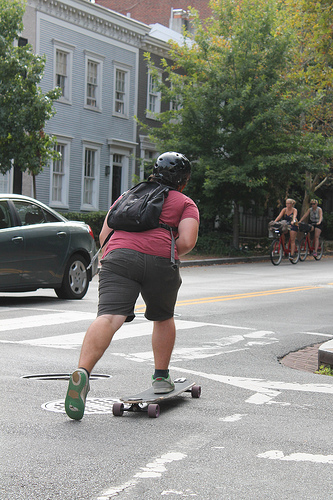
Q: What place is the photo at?
A: It is at the street.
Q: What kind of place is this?
A: It is a street.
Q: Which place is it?
A: It is a street.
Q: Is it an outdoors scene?
A: Yes, it is outdoors.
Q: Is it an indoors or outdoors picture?
A: It is outdoors.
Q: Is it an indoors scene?
A: No, it is outdoors.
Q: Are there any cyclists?
A: Yes, there is a cyclist.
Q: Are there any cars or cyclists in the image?
A: Yes, there is a cyclist.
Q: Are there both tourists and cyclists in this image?
A: No, there is a cyclist but no tourists.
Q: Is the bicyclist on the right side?
A: Yes, the bicyclist is on the right of the image.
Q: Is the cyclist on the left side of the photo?
A: No, the cyclist is on the right of the image.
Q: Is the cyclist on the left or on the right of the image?
A: The cyclist is on the right of the image.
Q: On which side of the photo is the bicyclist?
A: The bicyclist is on the right of the image.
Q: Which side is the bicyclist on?
A: The bicyclist is on the right of the image.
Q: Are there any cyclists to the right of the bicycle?
A: Yes, there is a cyclist to the right of the bicycle.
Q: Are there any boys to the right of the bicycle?
A: No, there is a cyclist to the right of the bicycle.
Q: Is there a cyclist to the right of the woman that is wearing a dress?
A: Yes, there is a cyclist to the right of the woman.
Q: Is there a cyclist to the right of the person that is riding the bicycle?
A: Yes, there is a cyclist to the right of the woman.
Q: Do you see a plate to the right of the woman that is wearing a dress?
A: No, there is a cyclist to the right of the woman.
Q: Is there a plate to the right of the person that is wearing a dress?
A: No, there is a cyclist to the right of the woman.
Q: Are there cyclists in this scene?
A: Yes, there is a cyclist.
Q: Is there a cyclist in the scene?
A: Yes, there is a cyclist.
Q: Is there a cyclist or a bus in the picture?
A: Yes, there is a cyclist.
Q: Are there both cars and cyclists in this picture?
A: Yes, there are both a cyclist and a car.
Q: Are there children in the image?
A: No, there are no children.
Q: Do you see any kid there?
A: No, there are no children.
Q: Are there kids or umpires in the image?
A: No, there are no kids or umpires.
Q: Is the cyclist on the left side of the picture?
A: No, the cyclist is on the right of the image.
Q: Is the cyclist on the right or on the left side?
A: The cyclist is on the right of the image.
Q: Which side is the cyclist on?
A: The cyclist is on the right of the image.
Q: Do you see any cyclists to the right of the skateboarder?
A: Yes, there is a cyclist to the right of the skateboarder.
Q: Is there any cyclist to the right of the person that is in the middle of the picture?
A: Yes, there is a cyclist to the right of the skateboarder.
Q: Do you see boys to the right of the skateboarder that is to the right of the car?
A: No, there is a cyclist to the right of the skateboarder.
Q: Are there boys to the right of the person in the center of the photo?
A: No, there is a cyclist to the right of the skateboarder.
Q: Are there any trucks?
A: No, there are no trucks.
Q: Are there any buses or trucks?
A: No, there are no trucks or buses.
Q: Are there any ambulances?
A: No, there are no ambulances.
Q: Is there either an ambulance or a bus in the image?
A: No, there are no ambulances or buses.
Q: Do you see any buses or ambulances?
A: No, there are no ambulances or buses.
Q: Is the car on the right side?
A: No, the car is on the left of the image.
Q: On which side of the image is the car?
A: The car is on the left of the image.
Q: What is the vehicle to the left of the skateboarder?
A: The vehicle is a car.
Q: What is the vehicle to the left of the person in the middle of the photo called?
A: The vehicle is a car.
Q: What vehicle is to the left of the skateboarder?
A: The vehicle is a car.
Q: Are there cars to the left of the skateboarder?
A: Yes, there is a car to the left of the skateboarder.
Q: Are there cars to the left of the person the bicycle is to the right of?
A: Yes, there is a car to the left of the skateboarder.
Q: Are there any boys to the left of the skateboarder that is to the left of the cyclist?
A: No, there is a car to the left of the skateboarder.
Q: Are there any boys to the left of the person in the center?
A: No, there is a car to the left of the skateboarder.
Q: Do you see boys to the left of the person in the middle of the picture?
A: No, there is a car to the left of the skateboarder.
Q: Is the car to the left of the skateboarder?
A: Yes, the car is to the left of the skateboarder.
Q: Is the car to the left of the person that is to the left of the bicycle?
A: Yes, the car is to the left of the skateboarder.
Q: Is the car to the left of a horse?
A: No, the car is to the left of the skateboarder.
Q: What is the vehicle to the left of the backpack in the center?
A: The vehicle is a car.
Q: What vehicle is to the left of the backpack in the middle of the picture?
A: The vehicle is a car.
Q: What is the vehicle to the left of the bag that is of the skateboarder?
A: The vehicle is a car.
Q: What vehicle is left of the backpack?
A: The vehicle is a car.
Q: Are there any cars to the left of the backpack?
A: Yes, there is a car to the left of the backpack.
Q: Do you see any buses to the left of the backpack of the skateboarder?
A: No, there is a car to the left of the backpack.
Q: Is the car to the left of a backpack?
A: Yes, the car is to the left of a backpack.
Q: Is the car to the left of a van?
A: No, the car is to the left of a backpack.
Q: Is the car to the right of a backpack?
A: No, the car is to the left of a backpack.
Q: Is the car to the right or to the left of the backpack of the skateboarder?
A: The car is to the left of the backpack.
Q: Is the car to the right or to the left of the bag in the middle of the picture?
A: The car is to the left of the backpack.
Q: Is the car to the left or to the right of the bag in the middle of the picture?
A: The car is to the left of the backpack.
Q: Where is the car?
A: The car is in the street.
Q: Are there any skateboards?
A: Yes, there is a skateboard.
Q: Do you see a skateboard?
A: Yes, there is a skateboard.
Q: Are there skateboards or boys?
A: Yes, there is a skateboard.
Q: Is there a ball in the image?
A: No, there are no balls.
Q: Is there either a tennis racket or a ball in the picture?
A: No, there are no balls or rackets.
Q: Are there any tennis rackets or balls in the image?
A: No, there are no balls or tennis rackets.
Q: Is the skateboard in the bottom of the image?
A: Yes, the skateboard is in the bottom of the image.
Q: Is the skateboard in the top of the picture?
A: No, the skateboard is in the bottom of the image.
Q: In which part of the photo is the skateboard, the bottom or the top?
A: The skateboard is in the bottom of the image.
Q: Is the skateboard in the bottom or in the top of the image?
A: The skateboard is in the bottom of the image.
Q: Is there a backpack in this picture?
A: Yes, there is a backpack.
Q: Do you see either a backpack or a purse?
A: Yes, there is a backpack.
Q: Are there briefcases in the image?
A: No, there are no briefcases.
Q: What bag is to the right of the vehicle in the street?
A: The bag is a backpack.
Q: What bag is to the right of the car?
A: The bag is a backpack.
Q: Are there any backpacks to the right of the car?
A: Yes, there is a backpack to the right of the car.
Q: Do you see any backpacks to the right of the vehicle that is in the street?
A: Yes, there is a backpack to the right of the car.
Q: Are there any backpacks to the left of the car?
A: No, the backpack is to the right of the car.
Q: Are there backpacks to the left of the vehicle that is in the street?
A: No, the backpack is to the right of the car.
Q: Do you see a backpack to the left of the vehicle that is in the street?
A: No, the backpack is to the right of the car.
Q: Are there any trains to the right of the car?
A: No, there is a backpack to the right of the car.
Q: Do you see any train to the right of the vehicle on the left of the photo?
A: No, there is a backpack to the right of the car.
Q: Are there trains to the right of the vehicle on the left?
A: No, there is a backpack to the right of the car.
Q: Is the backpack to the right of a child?
A: No, the backpack is to the right of the car.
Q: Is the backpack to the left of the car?
A: No, the backpack is to the right of the car.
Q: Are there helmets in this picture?
A: Yes, there is a helmet.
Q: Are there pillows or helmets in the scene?
A: Yes, there is a helmet.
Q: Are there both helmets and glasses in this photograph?
A: No, there is a helmet but no glasses.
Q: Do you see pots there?
A: No, there are no pots.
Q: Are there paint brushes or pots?
A: No, there are no pots or paint brushes.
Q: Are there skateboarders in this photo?
A: Yes, there is a skateboarder.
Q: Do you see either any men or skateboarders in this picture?
A: Yes, there is a skateboarder.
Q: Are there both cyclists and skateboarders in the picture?
A: Yes, there are both a skateboarder and a cyclist.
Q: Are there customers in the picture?
A: No, there are no customers.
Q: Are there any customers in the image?
A: No, there are no customers.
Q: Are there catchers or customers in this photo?
A: No, there are no customers or catchers.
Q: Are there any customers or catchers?
A: No, there are no customers or catchers.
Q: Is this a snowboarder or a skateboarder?
A: This is a skateboarder.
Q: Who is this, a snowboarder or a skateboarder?
A: This is a skateboarder.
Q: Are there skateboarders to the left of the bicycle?
A: Yes, there is a skateboarder to the left of the bicycle.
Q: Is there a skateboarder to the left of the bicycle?
A: Yes, there is a skateboarder to the left of the bicycle.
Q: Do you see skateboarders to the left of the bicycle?
A: Yes, there is a skateboarder to the left of the bicycle.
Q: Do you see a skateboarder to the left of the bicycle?
A: Yes, there is a skateboarder to the left of the bicycle.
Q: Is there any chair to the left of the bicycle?
A: No, there is a skateboarder to the left of the bicycle.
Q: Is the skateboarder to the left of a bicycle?
A: Yes, the skateboarder is to the left of a bicycle.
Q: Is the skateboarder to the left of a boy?
A: No, the skateboarder is to the left of a bicycle.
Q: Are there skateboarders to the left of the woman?
A: Yes, there is a skateboarder to the left of the woman.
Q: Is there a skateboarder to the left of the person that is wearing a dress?
A: Yes, there is a skateboarder to the left of the woman.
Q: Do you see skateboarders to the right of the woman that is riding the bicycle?
A: No, the skateboarder is to the left of the woman.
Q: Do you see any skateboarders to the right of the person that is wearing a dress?
A: No, the skateboarder is to the left of the woman.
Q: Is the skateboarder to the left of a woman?
A: Yes, the skateboarder is to the left of a woman.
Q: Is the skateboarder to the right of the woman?
A: No, the skateboarder is to the left of the woman.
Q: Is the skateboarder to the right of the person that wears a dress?
A: No, the skateboarder is to the left of the woman.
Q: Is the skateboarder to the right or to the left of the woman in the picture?
A: The skateboarder is to the left of the woman.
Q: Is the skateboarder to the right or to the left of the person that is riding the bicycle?
A: The skateboarder is to the left of the woman.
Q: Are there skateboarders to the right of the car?
A: Yes, there is a skateboarder to the right of the car.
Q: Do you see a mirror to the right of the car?
A: No, there is a skateboarder to the right of the car.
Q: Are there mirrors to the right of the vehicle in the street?
A: No, there is a skateboarder to the right of the car.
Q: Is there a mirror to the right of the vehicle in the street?
A: No, there is a skateboarder to the right of the car.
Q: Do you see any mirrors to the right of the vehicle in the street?
A: No, there is a skateboarder to the right of the car.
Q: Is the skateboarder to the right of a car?
A: Yes, the skateboarder is to the right of a car.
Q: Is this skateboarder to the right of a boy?
A: No, the skateboarder is to the right of a car.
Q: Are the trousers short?
A: Yes, the trousers are short.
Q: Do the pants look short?
A: Yes, the pants are short.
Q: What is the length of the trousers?
A: The trousers are short.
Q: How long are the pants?
A: The pants are short.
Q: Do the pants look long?
A: No, the pants are short.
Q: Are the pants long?
A: No, the pants are short.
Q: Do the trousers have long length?
A: No, the trousers are short.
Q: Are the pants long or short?
A: The pants are short.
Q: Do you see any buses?
A: No, there are no buses.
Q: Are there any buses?
A: No, there are no buses.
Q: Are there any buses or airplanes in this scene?
A: No, there are no buses or airplanes.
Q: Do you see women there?
A: Yes, there is a woman.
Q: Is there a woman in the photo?
A: Yes, there is a woman.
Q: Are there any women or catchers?
A: Yes, there is a woman.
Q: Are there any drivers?
A: No, there are no drivers.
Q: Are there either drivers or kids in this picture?
A: No, there are no drivers or kids.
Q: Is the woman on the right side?
A: Yes, the woman is on the right of the image.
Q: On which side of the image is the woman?
A: The woman is on the right of the image.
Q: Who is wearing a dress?
A: The woman is wearing a dress.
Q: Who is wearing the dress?
A: The woman is wearing a dress.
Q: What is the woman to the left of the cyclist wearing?
A: The woman is wearing a dress.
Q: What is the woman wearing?
A: The woman is wearing a dress.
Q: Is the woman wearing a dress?
A: Yes, the woman is wearing a dress.